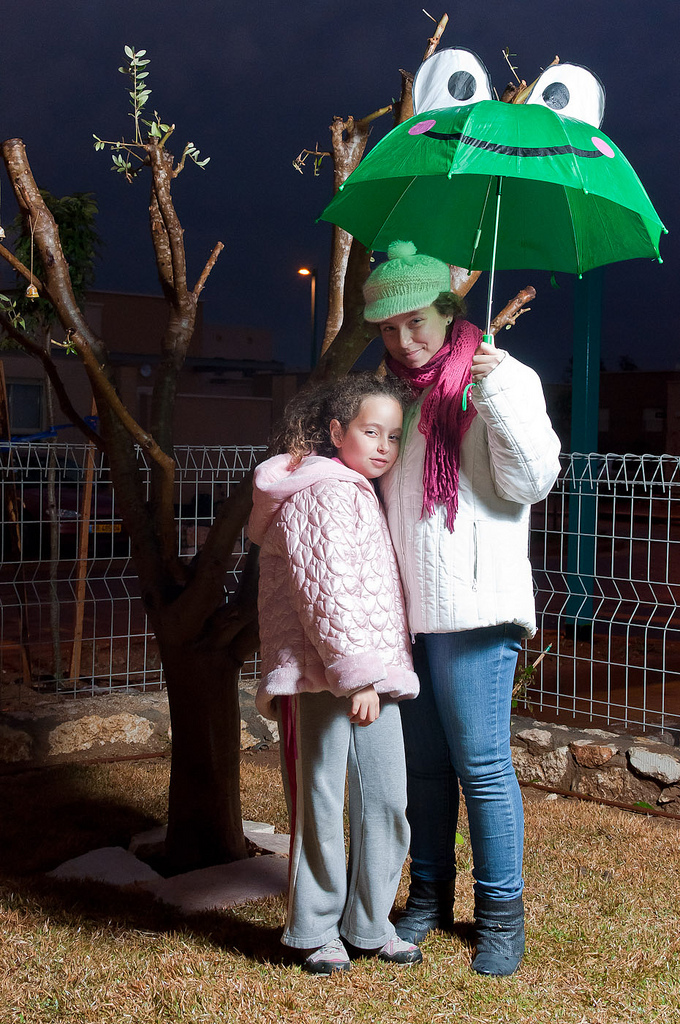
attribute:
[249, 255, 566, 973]
people — caucasian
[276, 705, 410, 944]
pants — gray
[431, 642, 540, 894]
jeans — blue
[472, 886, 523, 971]
boots — black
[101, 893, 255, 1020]
grass — mowed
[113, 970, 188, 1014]
grass — brown , green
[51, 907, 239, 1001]
grass — dry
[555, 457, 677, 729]
fence — wicker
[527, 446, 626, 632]
fence — metal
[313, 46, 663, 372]
umbrella — green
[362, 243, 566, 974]
lady — caucasian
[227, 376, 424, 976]
girl — caucasian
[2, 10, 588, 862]
tree — brown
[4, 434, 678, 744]
fence — metal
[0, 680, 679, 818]
rock — short 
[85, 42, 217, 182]
leaves — green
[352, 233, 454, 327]
hat — white 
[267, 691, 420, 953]
pants — grey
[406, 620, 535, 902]
jeans — blue 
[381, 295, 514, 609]
scarf — pink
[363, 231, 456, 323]
hat — white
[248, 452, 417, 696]
coat — pink